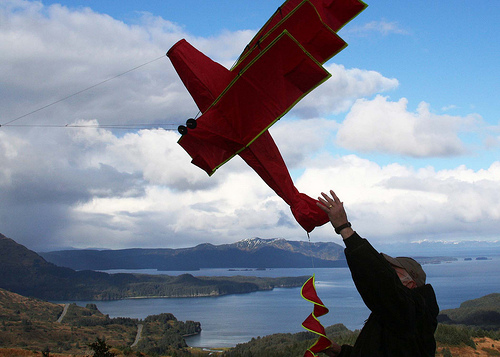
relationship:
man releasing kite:
[315, 189, 440, 356] [163, 0, 365, 233]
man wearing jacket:
[332, 192, 418, 308] [379, 289, 429, 348]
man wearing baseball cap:
[332, 192, 418, 308] [379, 252, 426, 287]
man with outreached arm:
[315, 189, 440, 356] [319, 187, 388, 324]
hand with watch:
[315, 189, 348, 229] [334, 221, 352, 234]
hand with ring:
[315, 189, 348, 229] [328, 204, 333, 208]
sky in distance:
[426, 43, 475, 98] [2, 1, 499, 238]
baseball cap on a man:
[379, 247, 436, 285] [276, 176, 468, 344]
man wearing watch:
[315, 189, 440, 356] [332, 218, 354, 235]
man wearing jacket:
[315, 189, 440, 356] [341, 230, 438, 350]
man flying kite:
[315, 189, 440, 356] [150, 0, 370, 353]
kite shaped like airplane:
[165, 0, 370, 356] [165, 0, 368, 233]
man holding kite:
[315, 189, 440, 356] [163, 0, 365, 233]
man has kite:
[315, 189, 440, 356] [150, 0, 370, 353]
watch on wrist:
[334, 221, 352, 234] [336, 214, 355, 240]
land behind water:
[32, 231, 490, 269] [46, 254, 498, 355]